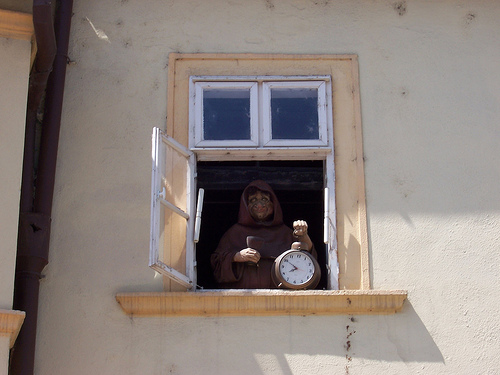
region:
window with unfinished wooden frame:
[113, 53, 405, 315]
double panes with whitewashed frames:
[185, 74, 332, 146]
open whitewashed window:
[148, 127, 195, 284]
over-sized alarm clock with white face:
[270, 242, 321, 291]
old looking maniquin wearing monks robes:
[212, 173, 314, 295]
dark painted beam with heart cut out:
[14, 40, 71, 372]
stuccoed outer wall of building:
[49, 50, 492, 373]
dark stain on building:
[342, 315, 361, 372]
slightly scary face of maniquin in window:
[241, 182, 277, 223]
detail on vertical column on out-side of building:
[1, 308, 25, 344]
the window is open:
[206, 159, 325, 274]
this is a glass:
[278, 89, 320, 131]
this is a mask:
[251, 193, 271, 215]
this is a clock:
[280, 253, 314, 280]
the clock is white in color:
[288, 256, 310, 276]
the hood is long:
[261, 221, 283, 236]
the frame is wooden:
[346, 163, 362, 235]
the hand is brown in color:
[293, 219, 307, 232]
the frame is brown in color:
[342, 134, 362, 166]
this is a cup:
[245, 232, 265, 249]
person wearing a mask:
[230, 178, 287, 229]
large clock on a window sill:
[275, 238, 347, 293]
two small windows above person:
[195, 78, 324, 147]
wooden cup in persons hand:
[238, 231, 265, 270]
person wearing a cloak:
[209, 175, 331, 293]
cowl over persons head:
[238, 180, 281, 224]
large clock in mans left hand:
[270, 218, 337, 289]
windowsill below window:
[115, 283, 427, 308]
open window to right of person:
[118, 119, 207, 300]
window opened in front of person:
[100, 41, 445, 321]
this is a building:
[23, 10, 486, 371]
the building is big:
[21, 0, 492, 372]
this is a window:
[146, 70, 328, 295]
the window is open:
[146, 57, 351, 288]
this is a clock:
[269, 240, 327, 290]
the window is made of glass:
[166, 163, 186, 200]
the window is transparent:
[163, 162, 181, 195]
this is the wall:
[381, 72, 495, 222]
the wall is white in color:
[378, 62, 455, 244]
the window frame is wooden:
[323, 121, 336, 198]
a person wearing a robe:
[200, 177, 320, 291]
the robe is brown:
[216, 184, 333, 299]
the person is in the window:
[147, 60, 422, 311]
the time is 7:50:
[265, 235, 336, 301]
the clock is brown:
[265, 245, 322, 295]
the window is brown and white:
[100, 35, 425, 328]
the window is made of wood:
[132, 42, 414, 325]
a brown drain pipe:
[20, 30, 106, 370]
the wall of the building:
[52, 38, 165, 372]